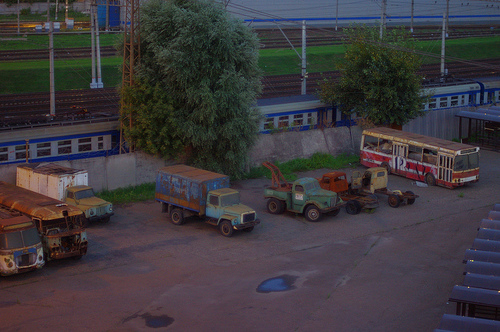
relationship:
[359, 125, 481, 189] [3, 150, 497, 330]
bus in parking lot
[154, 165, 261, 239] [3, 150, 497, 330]
blue truck in parking lot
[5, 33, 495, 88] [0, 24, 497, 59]
grass bordering tracks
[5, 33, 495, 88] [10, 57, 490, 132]
grass bordering tracks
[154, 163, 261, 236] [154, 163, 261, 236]
blue truck carrying part of blue truck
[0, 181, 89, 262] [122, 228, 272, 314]
bus in lot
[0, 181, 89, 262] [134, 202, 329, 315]
bus in lot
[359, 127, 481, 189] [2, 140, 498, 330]
bus in lot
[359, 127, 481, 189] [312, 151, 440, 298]
bus in lot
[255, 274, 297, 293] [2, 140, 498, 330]
puddle in lot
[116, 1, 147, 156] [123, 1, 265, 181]
tower by a tree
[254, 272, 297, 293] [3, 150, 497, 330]
puddle in a parking lot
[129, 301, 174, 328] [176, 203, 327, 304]
puddle drying in a lot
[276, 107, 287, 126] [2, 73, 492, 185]
window on a train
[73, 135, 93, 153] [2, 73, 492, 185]
window on a train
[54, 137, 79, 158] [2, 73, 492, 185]
window on a train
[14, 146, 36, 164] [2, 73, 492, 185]
window on a train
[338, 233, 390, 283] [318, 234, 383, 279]
cracks in pavement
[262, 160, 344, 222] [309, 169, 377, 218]
tow truck parked beside truck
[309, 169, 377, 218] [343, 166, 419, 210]
truck parked beside truck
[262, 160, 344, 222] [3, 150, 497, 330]
tow truck parked in parking lot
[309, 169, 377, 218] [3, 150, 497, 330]
truck parked in parking lot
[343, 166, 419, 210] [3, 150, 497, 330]
truck parked in parking lot